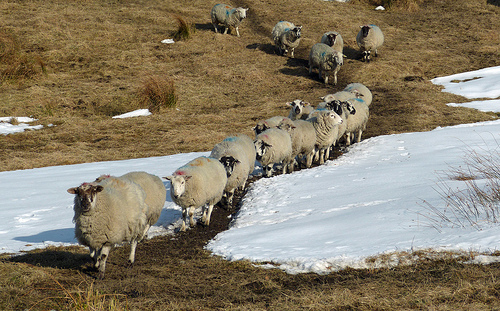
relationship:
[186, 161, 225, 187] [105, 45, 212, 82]
sheep in field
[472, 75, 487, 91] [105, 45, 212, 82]
snow in field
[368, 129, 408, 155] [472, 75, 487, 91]
footprints in snow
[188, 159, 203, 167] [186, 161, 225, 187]
spot on sheep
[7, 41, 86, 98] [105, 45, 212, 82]
grass in field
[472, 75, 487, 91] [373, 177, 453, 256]
snow on hill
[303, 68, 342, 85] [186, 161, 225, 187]
legs of sheep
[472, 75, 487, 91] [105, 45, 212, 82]
snow on field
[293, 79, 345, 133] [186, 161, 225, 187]
head of sheep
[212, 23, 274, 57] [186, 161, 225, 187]
feeet of sheep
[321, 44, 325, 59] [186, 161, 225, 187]
wool on sheep